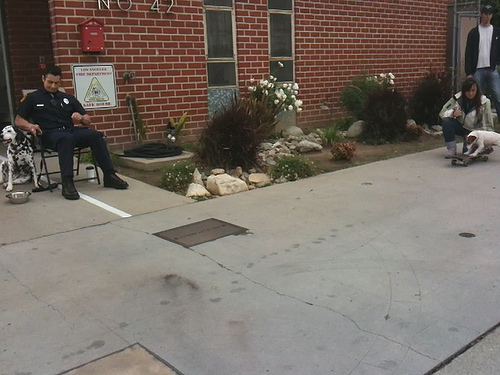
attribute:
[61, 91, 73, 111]
badge — silver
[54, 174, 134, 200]
shoes — black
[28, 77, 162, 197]
shirt — black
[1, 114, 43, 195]
dalmation — white, black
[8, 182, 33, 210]
dog bowl — silver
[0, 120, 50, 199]
dog — black, white, sitting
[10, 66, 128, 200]
man — sitting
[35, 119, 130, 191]
pants — black